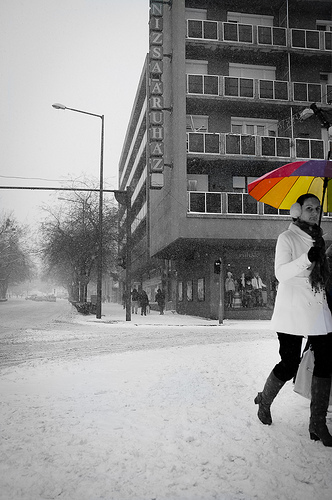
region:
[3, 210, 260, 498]
Snowy street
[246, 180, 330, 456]
Women in white coat and black boots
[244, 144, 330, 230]
A rainbow colored umbrella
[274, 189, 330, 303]
Women wearing ear muffs and a scarf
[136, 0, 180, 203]
A vertical sign on the side of a building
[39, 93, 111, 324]
Street light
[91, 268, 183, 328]
People walking on a snowy sidewalk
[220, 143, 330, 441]
A women with a rainbow umbrella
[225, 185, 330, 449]
A women crossing the street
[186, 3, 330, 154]
Balconies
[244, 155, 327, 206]
colorful umbrella top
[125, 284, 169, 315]
people on the sidewalk in the snow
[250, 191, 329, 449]
Young woman walking in snow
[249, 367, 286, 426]
snow boot on woman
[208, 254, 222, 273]
walk / don't walk sign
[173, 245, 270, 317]
storefront with window displays on street level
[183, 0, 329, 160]
Several apartment balconies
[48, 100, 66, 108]
street light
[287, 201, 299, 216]
ear muff on woman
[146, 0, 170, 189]
business sign on a building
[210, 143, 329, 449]
woman walking in snow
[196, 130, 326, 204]
colorful umbrella in a black and white photo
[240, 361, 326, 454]
snow boots with a 1 inch heel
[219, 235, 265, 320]
black and white photo of a store window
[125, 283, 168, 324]
people walking in snow storm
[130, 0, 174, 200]
Black and white sign photo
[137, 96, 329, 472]
woman holding a colorful umbrella in a black and white photo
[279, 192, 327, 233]
woman wearing earmuffs and a scarf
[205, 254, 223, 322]
black and white photo of traffic sign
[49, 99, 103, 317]
light pole on a street corner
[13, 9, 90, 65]
this is the sky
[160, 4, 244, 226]
this is a building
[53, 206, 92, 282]
this is a tree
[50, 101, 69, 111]
this is a lump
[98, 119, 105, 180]
this is a pole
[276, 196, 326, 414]
this is a lady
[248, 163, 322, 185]
this is an umbrella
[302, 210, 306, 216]
the lady is light skinned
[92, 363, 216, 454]
this is the ground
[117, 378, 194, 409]
the ground is white in color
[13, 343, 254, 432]
snow on the ground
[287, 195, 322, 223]
woman wearing ear muffs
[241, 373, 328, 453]
woman wearing dark boots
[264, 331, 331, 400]
woman wearing dark pants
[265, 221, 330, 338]
woman wearing a light colored coat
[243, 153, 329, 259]
woman holding umbrella, which is the only thing in color in the image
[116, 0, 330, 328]
tall building in the background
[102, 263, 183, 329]
people walking on sidewalk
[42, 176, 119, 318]
trees on the sidewalk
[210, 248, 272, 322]
mannequins in shop window